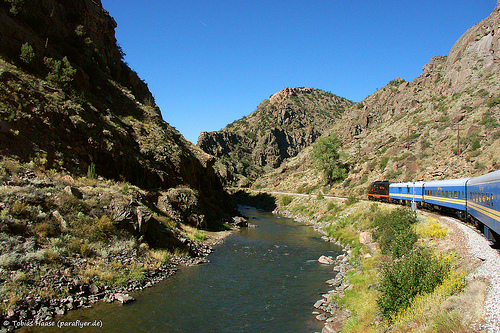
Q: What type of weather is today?
A: It is clear.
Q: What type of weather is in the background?
A: It is clear.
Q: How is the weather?
A: It is clear.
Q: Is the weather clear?
A: Yes, it is clear.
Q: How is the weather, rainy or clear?
A: It is clear.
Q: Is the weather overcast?
A: No, it is clear.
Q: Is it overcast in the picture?
A: No, it is clear.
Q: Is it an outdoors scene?
A: Yes, it is outdoors.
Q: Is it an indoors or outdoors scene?
A: It is outdoors.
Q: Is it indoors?
A: No, it is outdoors.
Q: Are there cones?
A: No, there are no cones.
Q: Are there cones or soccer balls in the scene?
A: No, there are no cones or soccer balls.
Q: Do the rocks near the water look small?
A: Yes, the rocks are small.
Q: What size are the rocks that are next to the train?
A: The rocks are small.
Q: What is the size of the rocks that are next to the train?
A: The rocks are small.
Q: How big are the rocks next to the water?
A: The rocks are small.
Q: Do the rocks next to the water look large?
A: No, the rocks are small.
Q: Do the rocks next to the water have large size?
A: No, the rocks are small.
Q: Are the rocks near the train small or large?
A: The rocks are small.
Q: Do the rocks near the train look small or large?
A: The rocks are small.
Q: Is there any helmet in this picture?
A: No, there are no helmets.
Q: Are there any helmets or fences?
A: No, there are no helmets or fences.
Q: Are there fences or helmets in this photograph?
A: No, there are no helmets or fences.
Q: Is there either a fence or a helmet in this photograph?
A: No, there are no helmets or fences.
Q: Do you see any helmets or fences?
A: No, there are no helmets or fences.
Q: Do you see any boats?
A: No, there are no boats.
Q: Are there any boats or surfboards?
A: No, there are no boats or surfboards.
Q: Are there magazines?
A: No, there are no magazines.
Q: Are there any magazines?
A: No, there are no magazines.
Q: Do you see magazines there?
A: No, there are no magazines.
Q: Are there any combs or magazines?
A: No, there are no magazines or combs.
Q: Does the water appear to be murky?
A: Yes, the water is murky.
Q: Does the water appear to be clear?
A: No, the water is murky.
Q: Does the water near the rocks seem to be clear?
A: No, the water is murky.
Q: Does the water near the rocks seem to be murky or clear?
A: The water is murky.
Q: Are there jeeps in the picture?
A: No, there are no jeeps.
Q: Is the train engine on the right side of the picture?
A: Yes, the train engine is on the right of the image.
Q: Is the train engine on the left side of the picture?
A: No, the train engine is on the right of the image.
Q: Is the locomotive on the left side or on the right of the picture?
A: The locomotive is on the right of the image.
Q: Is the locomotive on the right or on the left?
A: The locomotive is on the right of the image.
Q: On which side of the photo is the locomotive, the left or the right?
A: The locomotive is on the right of the image.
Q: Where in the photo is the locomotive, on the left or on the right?
A: The locomotive is on the right of the image.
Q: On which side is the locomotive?
A: The locomotive is on the right of the image.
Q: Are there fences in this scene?
A: No, there are no fences.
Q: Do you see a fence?
A: No, there are no fences.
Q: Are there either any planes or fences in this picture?
A: No, there are no fences or planes.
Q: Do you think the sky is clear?
A: Yes, the sky is clear.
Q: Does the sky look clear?
A: Yes, the sky is clear.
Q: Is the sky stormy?
A: No, the sky is clear.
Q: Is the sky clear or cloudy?
A: The sky is clear.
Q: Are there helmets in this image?
A: No, there are no helmets.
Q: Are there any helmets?
A: No, there are no helmets.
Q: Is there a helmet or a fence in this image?
A: No, there are no helmets or fences.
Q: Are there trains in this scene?
A: Yes, there is a train.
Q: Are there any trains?
A: Yes, there is a train.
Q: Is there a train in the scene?
A: Yes, there is a train.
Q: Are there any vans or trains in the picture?
A: Yes, there is a train.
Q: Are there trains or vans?
A: Yes, there is a train.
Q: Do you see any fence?
A: No, there are no fences.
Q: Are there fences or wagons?
A: No, there are no fences or wagons.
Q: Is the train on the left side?
A: No, the train is on the right of the image.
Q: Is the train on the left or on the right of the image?
A: The train is on the right of the image.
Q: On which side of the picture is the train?
A: The train is on the right of the image.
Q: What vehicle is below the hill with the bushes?
A: The vehicle is a train.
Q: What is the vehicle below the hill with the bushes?
A: The vehicle is a train.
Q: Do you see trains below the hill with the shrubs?
A: Yes, there is a train below the hill.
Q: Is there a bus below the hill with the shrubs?
A: No, there is a train below the hill.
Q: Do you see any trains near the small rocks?
A: Yes, there is a train near the rocks.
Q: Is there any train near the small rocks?
A: Yes, there is a train near the rocks.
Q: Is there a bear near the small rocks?
A: No, there is a train near the rocks.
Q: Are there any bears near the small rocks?
A: No, there is a train near the rocks.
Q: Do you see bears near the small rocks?
A: No, there is a train near the rocks.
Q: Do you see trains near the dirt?
A: Yes, there is a train near the dirt.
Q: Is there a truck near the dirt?
A: No, there is a train near the dirt.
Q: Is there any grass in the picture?
A: Yes, there is grass.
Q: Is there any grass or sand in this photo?
A: Yes, there is grass.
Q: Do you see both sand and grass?
A: No, there is grass but no sand.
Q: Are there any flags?
A: No, there are no flags.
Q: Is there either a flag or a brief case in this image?
A: No, there are no flags or briefcases.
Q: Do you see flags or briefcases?
A: No, there are no flags or briefcases.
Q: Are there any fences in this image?
A: No, there are no fences.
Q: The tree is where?
A: The tree is on the hill.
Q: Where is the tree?
A: The tree is on the hill.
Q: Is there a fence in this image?
A: No, there are no fences.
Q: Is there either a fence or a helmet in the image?
A: No, there are no fences or helmets.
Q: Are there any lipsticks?
A: No, there are no lipsticks.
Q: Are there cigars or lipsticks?
A: No, there are no lipsticks or cigars.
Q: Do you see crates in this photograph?
A: No, there are no crates.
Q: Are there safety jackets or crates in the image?
A: No, there are no crates or safety jackets.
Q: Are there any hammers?
A: No, there are no hammers.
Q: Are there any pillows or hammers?
A: No, there are no hammers or pillows.